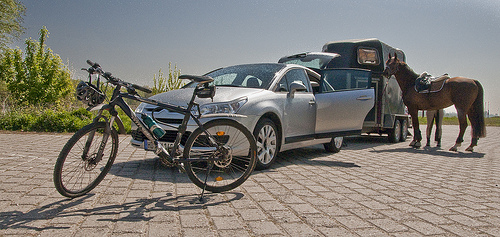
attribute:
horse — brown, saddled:
[380, 54, 488, 154]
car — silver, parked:
[129, 41, 346, 168]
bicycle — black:
[45, 48, 262, 199]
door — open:
[311, 64, 376, 140]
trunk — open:
[270, 48, 342, 71]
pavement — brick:
[3, 131, 496, 231]